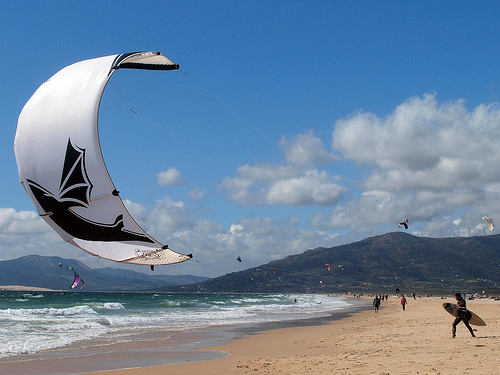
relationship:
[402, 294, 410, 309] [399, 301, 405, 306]
woman wears pants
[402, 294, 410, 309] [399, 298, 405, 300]
woman wears shirt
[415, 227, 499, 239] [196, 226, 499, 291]
wind farm on hill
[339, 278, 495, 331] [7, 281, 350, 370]
people in sea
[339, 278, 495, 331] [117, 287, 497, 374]
people near shore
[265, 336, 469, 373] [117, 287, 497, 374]
footprints in sand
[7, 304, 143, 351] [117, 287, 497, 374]
waves near shore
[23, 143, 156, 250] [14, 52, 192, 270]
image on kite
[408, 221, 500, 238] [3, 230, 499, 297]
windmills on mountains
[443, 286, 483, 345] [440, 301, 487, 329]
person carrying surfboard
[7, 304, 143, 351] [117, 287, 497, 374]
waves crash on shore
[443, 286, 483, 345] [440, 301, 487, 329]
surfer holding surfboard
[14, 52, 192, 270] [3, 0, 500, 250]
kite in air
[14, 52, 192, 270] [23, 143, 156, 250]
kite has dolphin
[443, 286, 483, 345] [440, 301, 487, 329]
man carries surfboard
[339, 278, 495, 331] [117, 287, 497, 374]
people on sand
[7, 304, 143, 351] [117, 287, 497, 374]
waves coming on shore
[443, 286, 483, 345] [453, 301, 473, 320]
person wearing wetsuit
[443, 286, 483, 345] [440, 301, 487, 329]
man has surfboard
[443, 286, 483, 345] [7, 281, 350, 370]
man going to water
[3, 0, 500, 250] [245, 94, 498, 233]
sky has clouds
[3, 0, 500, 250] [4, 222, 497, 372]
sky over land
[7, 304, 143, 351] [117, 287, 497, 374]
waves breaking on shore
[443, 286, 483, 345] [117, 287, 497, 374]
person walking in sand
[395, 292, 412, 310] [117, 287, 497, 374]
person walking in sand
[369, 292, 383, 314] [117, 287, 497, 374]
person walking in sand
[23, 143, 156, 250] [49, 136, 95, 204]
fish has fins